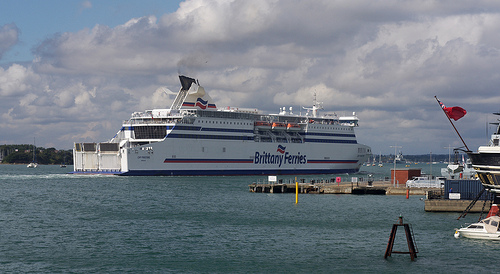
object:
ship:
[71, 75, 376, 174]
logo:
[254, 143, 308, 166]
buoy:
[385, 214, 419, 261]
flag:
[439, 103, 466, 122]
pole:
[432, 94, 472, 155]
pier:
[249, 181, 446, 195]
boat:
[57, 162, 67, 168]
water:
[1, 163, 500, 274]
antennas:
[302, 88, 324, 116]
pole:
[293, 178, 303, 205]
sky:
[1, 1, 498, 155]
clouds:
[0, 17, 26, 56]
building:
[389, 168, 422, 184]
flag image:
[276, 144, 288, 156]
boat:
[453, 214, 500, 242]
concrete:
[421, 198, 492, 211]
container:
[443, 178, 496, 202]